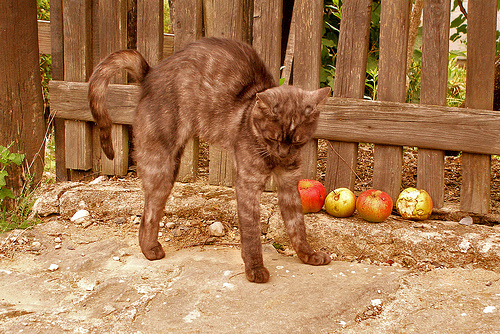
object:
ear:
[312, 87, 331, 106]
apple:
[396, 187, 434, 221]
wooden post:
[417, 0, 446, 209]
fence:
[43, 1, 499, 224]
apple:
[298, 179, 327, 212]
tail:
[88, 50, 153, 160]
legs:
[234, 161, 272, 284]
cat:
[87, 36, 332, 284]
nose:
[277, 145, 290, 158]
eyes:
[268, 136, 278, 143]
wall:
[51, 0, 499, 218]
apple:
[322, 187, 355, 218]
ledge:
[33, 175, 500, 266]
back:
[65, 1, 89, 82]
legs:
[276, 160, 311, 253]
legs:
[137, 143, 173, 250]